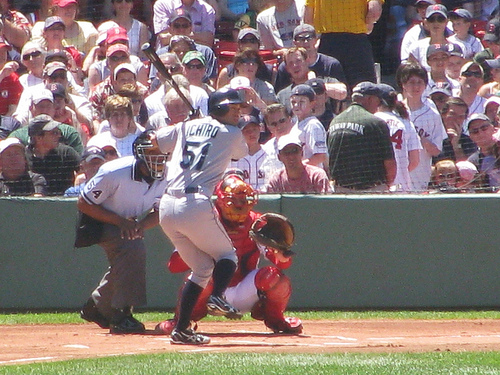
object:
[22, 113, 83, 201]
spectator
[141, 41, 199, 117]
bat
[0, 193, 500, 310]
wall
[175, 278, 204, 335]
sock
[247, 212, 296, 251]
baseball glove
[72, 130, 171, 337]
umpire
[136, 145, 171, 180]
mask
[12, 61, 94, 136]
man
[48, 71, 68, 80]
sunglasses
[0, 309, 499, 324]
grass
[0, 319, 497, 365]
dirt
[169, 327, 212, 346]
sneaker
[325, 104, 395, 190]
shirt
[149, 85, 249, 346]
baseball player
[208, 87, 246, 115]
helmet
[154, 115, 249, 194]
jersey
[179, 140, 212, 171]
number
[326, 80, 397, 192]
fan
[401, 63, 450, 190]
fan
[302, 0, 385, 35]
shirt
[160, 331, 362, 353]
box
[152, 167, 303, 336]
catcher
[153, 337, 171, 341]
plate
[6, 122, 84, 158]
shirt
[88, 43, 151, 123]
man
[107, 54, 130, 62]
sunglasses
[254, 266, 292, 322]
shin guard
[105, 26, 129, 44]
cap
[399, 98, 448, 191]
jersey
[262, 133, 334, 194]
spectators